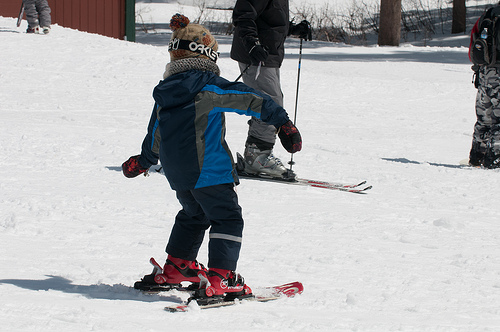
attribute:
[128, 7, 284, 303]
kid — playing, skiing, black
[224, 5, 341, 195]
person — tall, skiing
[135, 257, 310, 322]
skis — small, red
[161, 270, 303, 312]
skis — red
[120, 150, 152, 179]
mitten — red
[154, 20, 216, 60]
hat — Camouflage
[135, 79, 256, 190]
jacket — Blue, black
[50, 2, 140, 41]
building — red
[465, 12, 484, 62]
backpack — red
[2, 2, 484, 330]
snow — white, clear, green, gray, black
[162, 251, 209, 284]
ski boot — red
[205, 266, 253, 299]
ski boot — red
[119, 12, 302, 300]
child — small , learning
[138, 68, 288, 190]
jacket — warm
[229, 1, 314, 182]
man — skiing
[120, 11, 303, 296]
kid — balancing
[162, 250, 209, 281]
ski shoe — red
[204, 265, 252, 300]
ski shoe — red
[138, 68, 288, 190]
coat — blue, gray